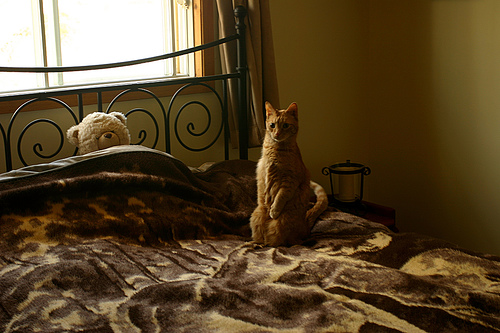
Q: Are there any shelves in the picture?
A: No, there are no shelves.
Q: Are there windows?
A: Yes, there is a window.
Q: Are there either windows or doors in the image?
A: Yes, there is a window.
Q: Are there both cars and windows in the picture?
A: No, there is a window but no cars.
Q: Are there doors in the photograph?
A: No, there are no doors.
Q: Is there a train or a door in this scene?
A: No, there are no doors or trains.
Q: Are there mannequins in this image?
A: No, there are no mannequins.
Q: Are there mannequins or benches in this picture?
A: No, there are no mannequins or benches.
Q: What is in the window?
A: The sun is in the window.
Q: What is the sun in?
A: The sun is in the window.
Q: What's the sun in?
A: The sun is in the window.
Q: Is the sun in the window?
A: Yes, the sun is in the window.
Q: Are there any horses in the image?
A: No, there are no horses.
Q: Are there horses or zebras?
A: No, there are no horses or zebras.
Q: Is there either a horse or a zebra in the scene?
A: No, there are no horses or zebras.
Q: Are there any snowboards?
A: No, there are no snowboards.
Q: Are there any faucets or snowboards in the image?
A: No, there are no snowboards or faucets.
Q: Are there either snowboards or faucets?
A: No, there are no snowboards or faucets.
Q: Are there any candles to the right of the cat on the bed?
A: Yes, there is a candle to the right of the cat.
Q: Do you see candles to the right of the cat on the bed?
A: Yes, there is a candle to the right of the cat.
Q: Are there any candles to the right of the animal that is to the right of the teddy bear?
A: Yes, there is a candle to the right of the cat.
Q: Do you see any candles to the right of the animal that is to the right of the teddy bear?
A: Yes, there is a candle to the right of the cat.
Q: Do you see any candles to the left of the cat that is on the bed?
A: No, the candle is to the right of the cat.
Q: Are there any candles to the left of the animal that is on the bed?
A: No, the candle is to the right of the cat.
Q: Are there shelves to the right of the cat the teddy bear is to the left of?
A: No, there is a candle to the right of the cat.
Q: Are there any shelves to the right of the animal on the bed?
A: No, there is a candle to the right of the cat.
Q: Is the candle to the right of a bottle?
A: No, the candle is to the right of a cat.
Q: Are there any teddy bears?
A: Yes, there is a teddy bear.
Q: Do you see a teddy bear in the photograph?
A: Yes, there is a teddy bear.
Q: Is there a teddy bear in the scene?
A: Yes, there is a teddy bear.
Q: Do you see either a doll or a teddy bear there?
A: Yes, there is a teddy bear.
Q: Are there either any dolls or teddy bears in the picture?
A: Yes, there is a teddy bear.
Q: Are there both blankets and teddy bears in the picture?
A: Yes, there are both a teddy bear and a blanket.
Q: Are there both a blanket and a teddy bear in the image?
A: Yes, there are both a teddy bear and a blanket.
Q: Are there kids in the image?
A: No, there are no kids.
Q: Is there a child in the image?
A: No, there are no children.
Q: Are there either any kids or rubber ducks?
A: No, there are no kids or rubber ducks.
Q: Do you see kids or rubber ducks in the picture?
A: No, there are no kids or rubber ducks.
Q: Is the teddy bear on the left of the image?
A: Yes, the teddy bear is on the left of the image.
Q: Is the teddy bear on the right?
A: No, the teddy bear is on the left of the image.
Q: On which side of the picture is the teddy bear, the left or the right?
A: The teddy bear is on the left of the image.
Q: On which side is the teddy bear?
A: The teddy bear is on the left of the image.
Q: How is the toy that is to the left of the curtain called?
A: The toy is a teddy bear.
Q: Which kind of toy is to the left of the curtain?
A: The toy is a teddy bear.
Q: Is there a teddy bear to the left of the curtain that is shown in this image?
A: Yes, there is a teddy bear to the left of the curtain.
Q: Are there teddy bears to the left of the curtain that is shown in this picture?
A: Yes, there is a teddy bear to the left of the curtain.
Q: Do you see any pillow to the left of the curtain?
A: No, there is a teddy bear to the left of the curtain.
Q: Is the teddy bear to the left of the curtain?
A: Yes, the teddy bear is to the left of the curtain.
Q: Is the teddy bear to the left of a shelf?
A: No, the teddy bear is to the left of the curtain.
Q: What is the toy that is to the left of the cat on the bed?
A: The toy is a teddy bear.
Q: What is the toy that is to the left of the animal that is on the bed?
A: The toy is a teddy bear.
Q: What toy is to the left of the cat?
A: The toy is a teddy bear.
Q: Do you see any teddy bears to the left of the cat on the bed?
A: Yes, there is a teddy bear to the left of the cat.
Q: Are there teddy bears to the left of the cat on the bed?
A: Yes, there is a teddy bear to the left of the cat.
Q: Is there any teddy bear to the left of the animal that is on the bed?
A: Yes, there is a teddy bear to the left of the cat.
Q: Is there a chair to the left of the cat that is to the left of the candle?
A: No, there is a teddy bear to the left of the cat.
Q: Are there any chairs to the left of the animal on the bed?
A: No, there is a teddy bear to the left of the cat.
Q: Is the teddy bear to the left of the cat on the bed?
A: Yes, the teddy bear is to the left of the cat.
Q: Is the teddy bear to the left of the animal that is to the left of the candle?
A: Yes, the teddy bear is to the left of the cat.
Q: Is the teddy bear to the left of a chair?
A: No, the teddy bear is to the left of the cat.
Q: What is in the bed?
A: The teddy bear is in the bed.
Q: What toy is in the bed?
A: The toy is a teddy bear.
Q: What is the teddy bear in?
A: The teddy bear is in the bed.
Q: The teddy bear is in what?
A: The teddy bear is in the bed.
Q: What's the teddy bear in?
A: The teddy bear is in the bed.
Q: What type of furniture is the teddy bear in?
A: The teddy bear is in the bed.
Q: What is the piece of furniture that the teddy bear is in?
A: The piece of furniture is a bed.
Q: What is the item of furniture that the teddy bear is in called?
A: The piece of furniture is a bed.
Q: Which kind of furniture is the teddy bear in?
A: The teddy bear is in the bed.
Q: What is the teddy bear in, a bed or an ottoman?
A: The teddy bear is in a bed.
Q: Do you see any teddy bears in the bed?
A: Yes, there is a teddy bear in the bed.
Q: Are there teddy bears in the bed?
A: Yes, there is a teddy bear in the bed.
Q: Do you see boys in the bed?
A: No, there is a teddy bear in the bed.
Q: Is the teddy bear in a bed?
A: Yes, the teddy bear is in a bed.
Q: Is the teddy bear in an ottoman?
A: No, the teddy bear is in a bed.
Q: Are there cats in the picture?
A: Yes, there is a cat.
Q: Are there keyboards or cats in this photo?
A: Yes, there is a cat.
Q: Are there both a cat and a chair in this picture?
A: No, there is a cat but no chairs.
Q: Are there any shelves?
A: No, there are no shelves.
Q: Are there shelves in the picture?
A: No, there are no shelves.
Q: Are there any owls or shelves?
A: No, there are no shelves or owls.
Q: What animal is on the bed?
A: The cat is on the bed.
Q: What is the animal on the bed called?
A: The animal is a cat.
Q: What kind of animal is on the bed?
A: The animal is a cat.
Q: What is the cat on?
A: The cat is on the bed.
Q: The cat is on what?
A: The cat is on the bed.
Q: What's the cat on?
A: The cat is on the bed.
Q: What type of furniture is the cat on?
A: The cat is on the bed.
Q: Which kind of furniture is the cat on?
A: The cat is on the bed.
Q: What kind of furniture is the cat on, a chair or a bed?
A: The cat is on a bed.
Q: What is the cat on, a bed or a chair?
A: The cat is on a bed.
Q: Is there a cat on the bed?
A: Yes, there is a cat on the bed.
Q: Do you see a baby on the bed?
A: No, there is a cat on the bed.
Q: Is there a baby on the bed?
A: No, there is a cat on the bed.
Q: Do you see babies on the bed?
A: No, there is a cat on the bed.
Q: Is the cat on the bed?
A: Yes, the cat is on the bed.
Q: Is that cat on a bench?
A: No, the cat is on the bed.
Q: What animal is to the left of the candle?
A: The animal is a cat.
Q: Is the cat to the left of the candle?
A: Yes, the cat is to the left of the candle.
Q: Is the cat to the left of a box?
A: No, the cat is to the left of the candle.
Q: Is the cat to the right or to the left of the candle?
A: The cat is to the left of the candle.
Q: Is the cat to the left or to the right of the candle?
A: The cat is to the left of the candle.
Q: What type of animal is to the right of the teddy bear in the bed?
A: The animal is a cat.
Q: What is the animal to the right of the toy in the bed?
A: The animal is a cat.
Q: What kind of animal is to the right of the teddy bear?
A: The animal is a cat.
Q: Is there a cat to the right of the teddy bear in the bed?
A: Yes, there is a cat to the right of the teddy bear.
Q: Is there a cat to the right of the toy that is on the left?
A: Yes, there is a cat to the right of the teddy bear.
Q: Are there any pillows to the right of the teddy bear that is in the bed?
A: No, there is a cat to the right of the teddy bear.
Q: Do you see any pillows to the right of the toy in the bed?
A: No, there is a cat to the right of the teddy bear.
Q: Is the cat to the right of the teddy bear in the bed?
A: Yes, the cat is to the right of the teddy bear.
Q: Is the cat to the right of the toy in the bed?
A: Yes, the cat is to the right of the teddy bear.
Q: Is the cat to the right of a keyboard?
A: No, the cat is to the right of the teddy bear.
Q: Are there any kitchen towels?
A: No, there are no kitchen towels.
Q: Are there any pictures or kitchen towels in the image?
A: No, there are no kitchen towels or pictures.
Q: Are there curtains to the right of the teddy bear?
A: Yes, there is a curtain to the right of the teddy bear.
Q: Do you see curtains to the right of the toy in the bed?
A: Yes, there is a curtain to the right of the teddy bear.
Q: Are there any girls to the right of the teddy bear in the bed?
A: No, there is a curtain to the right of the teddy bear.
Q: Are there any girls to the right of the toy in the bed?
A: No, there is a curtain to the right of the teddy bear.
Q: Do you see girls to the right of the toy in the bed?
A: No, there is a curtain to the right of the teddy bear.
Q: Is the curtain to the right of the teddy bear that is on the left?
A: Yes, the curtain is to the right of the teddy bear.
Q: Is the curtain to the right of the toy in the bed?
A: Yes, the curtain is to the right of the teddy bear.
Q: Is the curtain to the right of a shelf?
A: No, the curtain is to the right of the teddy bear.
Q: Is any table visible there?
A: Yes, there is a table.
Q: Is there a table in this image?
A: Yes, there is a table.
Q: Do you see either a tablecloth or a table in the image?
A: Yes, there is a table.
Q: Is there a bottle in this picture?
A: No, there are no bottles.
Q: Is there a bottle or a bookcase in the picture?
A: No, there are no bottles or bookcases.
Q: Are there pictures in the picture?
A: No, there are no pictures.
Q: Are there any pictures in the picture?
A: No, there are no pictures.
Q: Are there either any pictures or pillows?
A: No, there are no pictures or pillows.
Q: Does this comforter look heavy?
A: Yes, the comforter is heavy.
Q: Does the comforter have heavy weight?
A: Yes, the comforter is heavy.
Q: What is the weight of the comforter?
A: The bed cover is heavy.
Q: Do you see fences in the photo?
A: No, there are no fences.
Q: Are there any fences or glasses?
A: No, there are no fences or glasses.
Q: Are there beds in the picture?
A: Yes, there is a bed.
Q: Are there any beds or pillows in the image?
A: Yes, there is a bed.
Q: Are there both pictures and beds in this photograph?
A: No, there is a bed but no pictures.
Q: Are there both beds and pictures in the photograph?
A: No, there is a bed but no pictures.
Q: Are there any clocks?
A: No, there are no clocks.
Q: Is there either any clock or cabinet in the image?
A: No, there are no clocks or cabinets.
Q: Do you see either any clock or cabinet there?
A: No, there are no clocks or cabinets.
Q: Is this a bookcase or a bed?
A: This is a bed.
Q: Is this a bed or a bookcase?
A: This is a bed.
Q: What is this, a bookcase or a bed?
A: This is a bed.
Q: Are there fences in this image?
A: No, there are no fences.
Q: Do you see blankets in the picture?
A: Yes, there is a blanket.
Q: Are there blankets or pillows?
A: Yes, there is a blanket.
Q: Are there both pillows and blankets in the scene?
A: No, there is a blanket but no pillows.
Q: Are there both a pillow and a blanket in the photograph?
A: No, there is a blanket but no pillows.